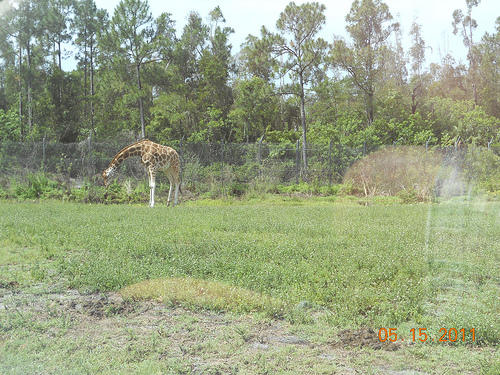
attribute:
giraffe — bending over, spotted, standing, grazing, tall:
[100, 135, 192, 206]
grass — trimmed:
[1, 191, 499, 372]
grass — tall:
[1, 171, 499, 202]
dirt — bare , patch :
[10, 286, 348, 363]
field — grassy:
[1, 173, 498, 373]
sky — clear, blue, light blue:
[1, 1, 499, 108]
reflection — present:
[95, 276, 281, 317]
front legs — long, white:
[143, 165, 158, 207]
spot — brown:
[130, 146, 139, 154]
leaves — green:
[404, 18, 436, 74]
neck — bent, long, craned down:
[108, 140, 141, 168]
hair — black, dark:
[177, 185, 186, 197]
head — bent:
[100, 163, 120, 187]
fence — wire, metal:
[2, 138, 500, 201]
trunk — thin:
[293, 52, 313, 174]